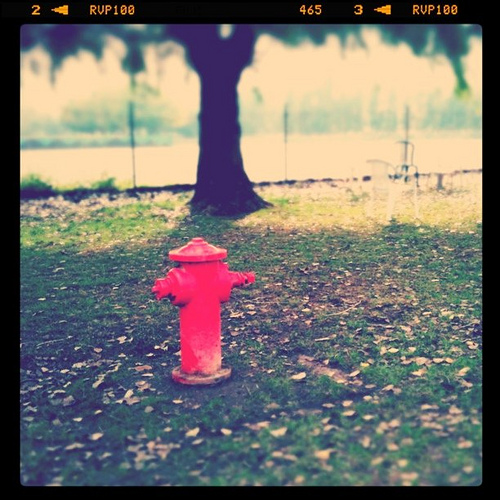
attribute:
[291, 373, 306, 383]
leaf — dry, brown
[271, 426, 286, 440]
leaf — dry, brown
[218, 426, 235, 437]
leaf — dry, brown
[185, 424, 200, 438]
leaf — dry, brown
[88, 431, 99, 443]
leaf — dry, brown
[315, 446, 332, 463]
leaf — dry, brown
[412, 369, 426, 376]
leaf — dry, brown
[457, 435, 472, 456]
leaf — dry, brown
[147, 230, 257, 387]
fire hydrant — dark, pink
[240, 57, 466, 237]
fence — out of focus 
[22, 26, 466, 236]
tree — green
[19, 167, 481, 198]
fence — black, metal, link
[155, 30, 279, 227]
tree — large 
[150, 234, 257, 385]
hydrant — red, metal, fire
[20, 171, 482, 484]
grass — dark, green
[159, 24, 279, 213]
tree — large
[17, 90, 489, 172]
fence — metal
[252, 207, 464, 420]
leaves — brown, dead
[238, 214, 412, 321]
boughs — lower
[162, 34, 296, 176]
tree — large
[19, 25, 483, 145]
sky — white, bright, clear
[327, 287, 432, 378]
leaves — green, blurry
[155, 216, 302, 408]
hydrant — pinky red, supersaturated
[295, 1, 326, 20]
numbers — yellow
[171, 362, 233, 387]
base —  rusty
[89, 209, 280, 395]
hydrant — orange, fire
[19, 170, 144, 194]
bushes — green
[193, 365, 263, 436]
circle — grassless, leafless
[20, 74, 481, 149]
bushes — green 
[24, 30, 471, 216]
background — blurred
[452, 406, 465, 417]
leaf — brown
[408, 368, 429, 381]
leaf — brown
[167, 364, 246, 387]
pedestal — small